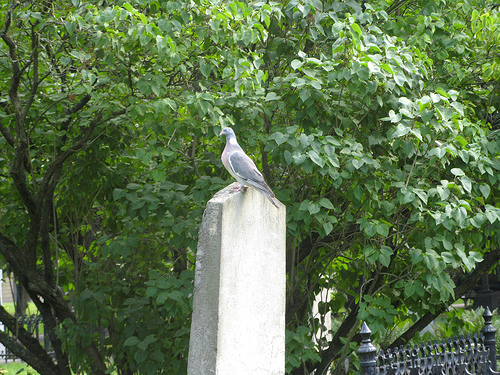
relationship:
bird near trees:
[209, 115, 272, 180] [275, 19, 462, 172]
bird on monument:
[209, 115, 272, 180] [183, 181, 289, 375]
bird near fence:
[209, 115, 272, 180] [359, 327, 500, 368]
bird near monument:
[209, 115, 272, 180] [183, 181, 289, 375]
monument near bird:
[183, 181, 289, 375] [209, 115, 272, 180]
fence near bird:
[359, 327, 500, 368] [209, 115, 272, 180]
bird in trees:
[209, 115, 272, 180] [275, 19, 462, 172]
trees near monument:
[275, 19, 462, 172] [183, 181, 289, 375]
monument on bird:
[183, 181, 289, 375] [209, 115, 272, 180]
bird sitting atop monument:
[209, 115, 272, 180] [186, 181, 287, 373]